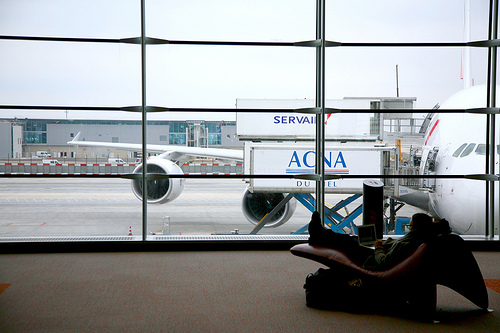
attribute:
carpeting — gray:
[7, 252, 498, 323]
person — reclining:
[311, 205, 454, 275]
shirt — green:
[374, 232, 418, 268]